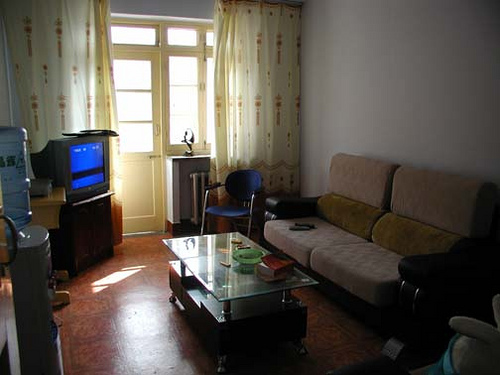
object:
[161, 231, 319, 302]
glass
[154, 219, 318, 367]
table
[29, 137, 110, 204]
television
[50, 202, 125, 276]
small table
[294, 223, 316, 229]
remote controls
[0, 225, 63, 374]
water dispenser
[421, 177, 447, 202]
ground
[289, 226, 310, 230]
controls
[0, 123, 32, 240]
water jug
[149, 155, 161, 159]
bracket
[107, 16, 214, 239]
door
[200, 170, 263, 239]
chair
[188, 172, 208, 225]
radiator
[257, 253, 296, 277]
book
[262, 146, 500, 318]
love seat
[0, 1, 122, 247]
curtain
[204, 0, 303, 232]
curtain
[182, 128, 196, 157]
trophy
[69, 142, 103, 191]
color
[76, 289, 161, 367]
flooring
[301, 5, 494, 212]
walls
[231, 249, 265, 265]
bowl